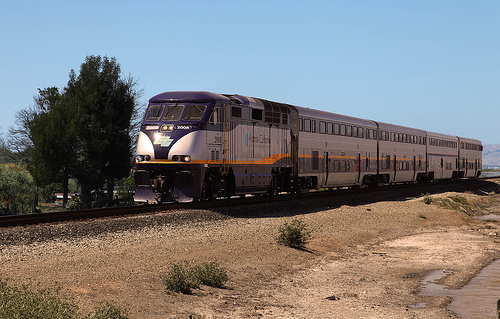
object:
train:
[133, 91, 483, 205]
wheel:
[295, 186, 309, 193]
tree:
[96, 57, 140, 207]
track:
[1, 175, 500, 227]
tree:
[64, 53, 119, 207]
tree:
[9, 86, 72, 208]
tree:
[1, 164, 39, 215]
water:
[409, 259, 500, 319]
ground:
[1, 180, 499, 318]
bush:
[277, 216, 316, 247]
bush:
[193, 264, 229, 288]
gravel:
[1, 201, 311, 245]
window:
[304, 118, 311, 131]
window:
[319, 120, 325, 134]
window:
[333, 122, 339, 135]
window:
[327, 121, 332, 134]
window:
[312, 120, 316, 133]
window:
[300, 118, 303, 131]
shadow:
[196, 178, 499, 218]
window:
[341, 125, 346, 135]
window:
[346, 125, 351, 136]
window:
[146, 106, 164, 122]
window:
[162, 104, 184, 122]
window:
[180, 104, 207, 120]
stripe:
[137, 153, 427, 164]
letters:
[250, 134, 268, 143]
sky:
[1, 1, 499, 145]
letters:
[153, 136, 174, 147]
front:
[136, 122, 199, 164]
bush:
[162, 266, 196, 293]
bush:
[0, 283, 125, 319]